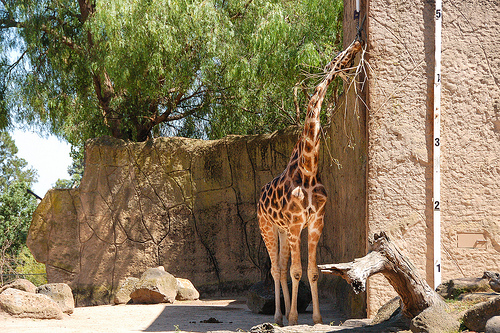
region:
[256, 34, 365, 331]
giraffe eat branch over head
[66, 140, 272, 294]
large beige rock wall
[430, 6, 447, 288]
measuring stick on side of wall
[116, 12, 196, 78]
green leaves on trees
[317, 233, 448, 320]
tree stump on the ground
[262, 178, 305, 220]
brown and white spots on giraffe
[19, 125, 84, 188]
clear blue sky behind trees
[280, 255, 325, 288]
knobby knees on front legs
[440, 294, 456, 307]
moss growing on tree stump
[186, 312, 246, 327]
pile of poop on ground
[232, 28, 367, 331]
The giraffe is eating.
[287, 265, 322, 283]
Dark brown on the knees.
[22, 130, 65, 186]
The sky is white.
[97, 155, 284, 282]
Wall behind the giraffe.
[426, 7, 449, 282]
Numbers on a tape measure.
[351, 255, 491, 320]
A log on the ground.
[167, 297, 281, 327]
Wall is casting a shadow.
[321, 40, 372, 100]
Branches on the wall.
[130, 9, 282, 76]
The tree is green.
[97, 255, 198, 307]
Rocks in front of the wall.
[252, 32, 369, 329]
A tall brown and white giraffe.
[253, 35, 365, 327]
Giraffe eating out of a tall window.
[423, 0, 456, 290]
Ruler on the wall to calculate height.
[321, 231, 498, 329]
Large piece of drift wood on the ground.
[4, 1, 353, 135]
Fully leaved green tree.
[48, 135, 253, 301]
Large brown stone wall.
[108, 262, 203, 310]
Very large rocks sitting on the ground.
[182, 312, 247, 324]
Giraffe scat on the ground in a pile.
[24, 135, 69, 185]
White cloud in the blue sky above.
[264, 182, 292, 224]
Dark brown spots on the giraffe.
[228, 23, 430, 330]
a giraffe in a zoo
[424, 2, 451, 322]
a meter pole for measuring giraffes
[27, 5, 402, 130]
trees with green leaves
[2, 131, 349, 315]
the rocks are brown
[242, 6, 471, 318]
the giraffe is eating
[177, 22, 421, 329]
the giraffe is tall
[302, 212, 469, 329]
an old stick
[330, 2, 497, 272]
a brown wall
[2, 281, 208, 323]
rocks on the ground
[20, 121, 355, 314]
the wall is cracked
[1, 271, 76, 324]
large round brown stones